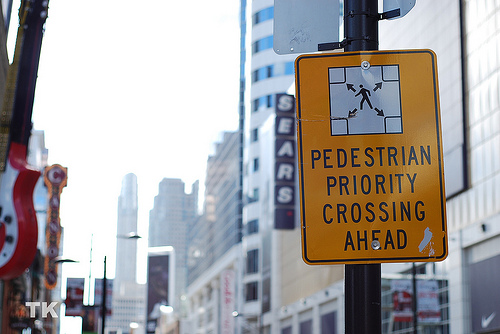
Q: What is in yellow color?
A: A crossing sign.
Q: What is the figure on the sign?
A: A person.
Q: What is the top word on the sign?
A: Pedestrian.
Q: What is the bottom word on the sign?
A: Ahead.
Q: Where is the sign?
A: On the post.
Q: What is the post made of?
A: Metal.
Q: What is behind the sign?
A: Buildings.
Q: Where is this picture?
A: A city.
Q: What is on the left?
A: A guitar.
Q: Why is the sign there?
A: To warn cars.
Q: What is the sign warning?
A: Pedestrians crossing.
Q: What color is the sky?
A: The sky is white in color.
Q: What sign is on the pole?
A: A pedestrian priority crossing ahead sign.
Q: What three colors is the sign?
A: The three colors of the sign is black, white, and orange.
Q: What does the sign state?
A: The sign says pedestrian priority crossing ahead.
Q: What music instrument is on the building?
A: A guitar.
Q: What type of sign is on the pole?
A: A pedestrian crossing sign.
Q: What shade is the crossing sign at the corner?
A: The crossing sign is yellow.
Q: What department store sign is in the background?
A: Sears.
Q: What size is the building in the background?
A: Tall.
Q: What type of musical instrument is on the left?
A: A guitar.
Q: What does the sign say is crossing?
A: Pedestrians.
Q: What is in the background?
A: Skyline.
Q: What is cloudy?
A: Background.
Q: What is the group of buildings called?
A: Skyscrapers.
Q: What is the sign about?
A: Pedestrian crossing.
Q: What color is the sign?
A: Yellow.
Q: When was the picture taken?
A: During the day.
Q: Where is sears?
A: The background.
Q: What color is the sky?
A: Grey.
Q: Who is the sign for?
A: Drivers.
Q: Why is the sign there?
A: To alert drivers.